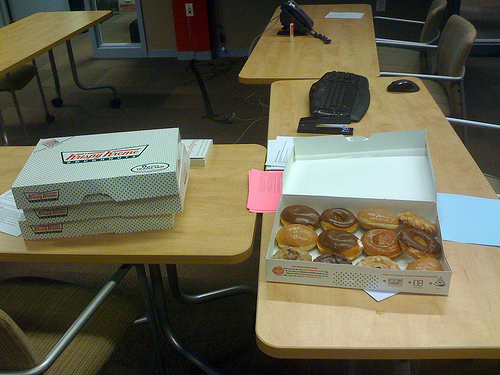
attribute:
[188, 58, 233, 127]
tape — black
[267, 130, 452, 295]
box — open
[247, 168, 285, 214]
paper — pink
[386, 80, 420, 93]
mouse — wireless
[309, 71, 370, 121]
keyboard — wireless, black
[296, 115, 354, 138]
stapler — black